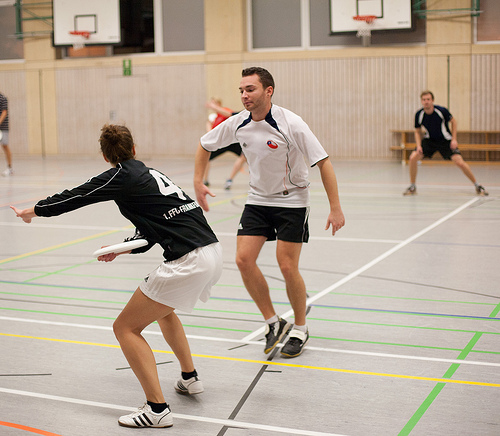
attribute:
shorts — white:
[137, 241, 224, 312]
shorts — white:
[1, 132, 11, 147]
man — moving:
[193, 67, 344, 358]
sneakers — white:
[117, 377, 204, 428]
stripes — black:
[133, 413, 152, 428]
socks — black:
[147, 370, 197, 412]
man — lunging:
[403, 92, 488, 197]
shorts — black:
[235, 205, 309, 243]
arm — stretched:
[11, 175, 116, 225]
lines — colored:
[312, 234, 493, 383]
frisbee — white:
[94, 239, 148, 258]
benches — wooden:
[391, 128, 497, 162]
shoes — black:
[265, 319, 309, 359]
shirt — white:
[200, 105, 330, 209]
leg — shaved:
[114, 288, 176, 403]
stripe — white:
[433, 107, 452, 142]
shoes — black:
[402, 184, 490, 196]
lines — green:
[317, 319, 498, 348]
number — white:
[148, 169, 186, 200]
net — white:
[357, 21, 375, 40]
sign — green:
[123, 60, 133, 77]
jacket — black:
[35, 159, 218, 260]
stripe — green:
[400, 353, 465, 434]